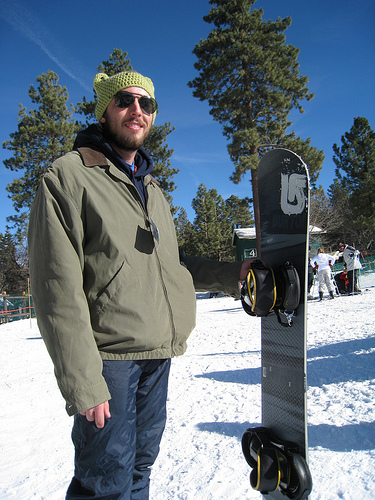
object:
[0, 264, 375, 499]
snow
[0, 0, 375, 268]
sky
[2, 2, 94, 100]
thin clouds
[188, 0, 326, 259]
trees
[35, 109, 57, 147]
leaves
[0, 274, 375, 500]
ground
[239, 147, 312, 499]
snowboard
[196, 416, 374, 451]
shadow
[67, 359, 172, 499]
pants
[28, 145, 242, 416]
jacket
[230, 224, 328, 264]
building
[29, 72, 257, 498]
man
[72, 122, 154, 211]
sweatshirt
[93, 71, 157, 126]
hat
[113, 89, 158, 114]
sunglasses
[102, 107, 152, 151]
beard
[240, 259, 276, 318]
foot holders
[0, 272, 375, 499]
tracks